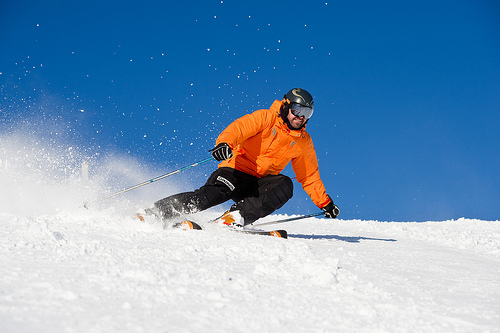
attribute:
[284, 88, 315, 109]
helmet — black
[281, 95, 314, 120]
goggles — black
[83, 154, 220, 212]
pole — silver, blue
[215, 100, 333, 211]
coat — orange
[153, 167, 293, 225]
pants — black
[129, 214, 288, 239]
skies — black, orange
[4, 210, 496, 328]
snow — white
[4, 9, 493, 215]
air — blue, clear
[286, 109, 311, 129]
face — hairy